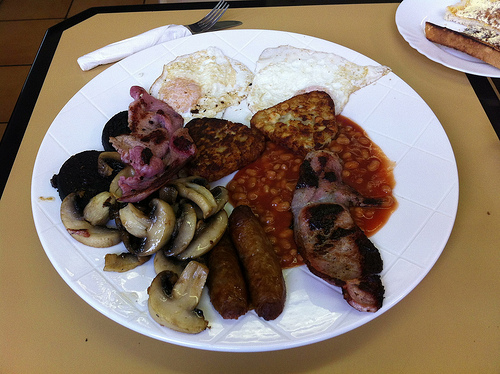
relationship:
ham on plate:
[291, 146, 390, 309] [31, 28, 459, 354]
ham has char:
[291, 146, 390, 309] [351, 235, 386, 295]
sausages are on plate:
[207, 207, 283, 320] [31, 28, 459, 354]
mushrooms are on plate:
[61, 180, 228, 332] [31, 28, 459, 354]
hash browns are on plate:
[187, 90, 337, 177] [31, 28, 459, 354]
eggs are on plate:
[157, 44, 352, 120] [31, 28, 459, 354]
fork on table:
[72, 0, 229, 67] [0, 1, 499, 372]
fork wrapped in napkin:
[72, 0, 229, 67] [75, 23, 190, 69]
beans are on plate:
[230, 115, 396, 263] [31, 28, 459, 354]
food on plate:
[58, 53, 388, 317] [31, 28, 459, 354]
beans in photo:
[230, 115, 396, 263] [0, 0, 498, 373]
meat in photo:
[213, 152, 385, 320] [0, 0, 498, 373]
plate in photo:
[31, 28, 459, 354] [0, 0, 498, 373]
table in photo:
[0, 1, 499, 372] [0, 0, 498, 373]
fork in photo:
[72, 0, 229, 67] [0, 0, 498, 373]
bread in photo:
[424, 0, 500, 70] [0, 0, 498, 373]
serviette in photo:
[75, 23, 190, 69] [0, 0, 498, 373]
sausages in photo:
[207, 207, 283, 320] [0, 0, 498, 373]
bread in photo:
[427, 0, 500, 66] [0, 0, 498, 373]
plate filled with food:
[31, 28, 459, 354] [58, 53, 388, 317]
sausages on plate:
[207, 207, 283, 320] [31, 28, 459, 354]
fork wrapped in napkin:
[76, 0, 229, 74] [75, 23, 190, 69]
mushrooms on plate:
[61, 180, 228, 332] [31, 28, 459, 354]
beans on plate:
[230, 115, 396, 263] [31, 28, 459, 354]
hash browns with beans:
[187, 90, 337, 177] [230, 115, 396, 263]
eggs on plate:
[157, 44, 352, 120] [31, 28, 459, 354]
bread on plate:
[427, 0, 500, 66] [394, 2, 499, 78]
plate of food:
[31, 28, 459, 354] [58, 53, 388, 317]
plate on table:
[31, 28, 459, 354] [0, 1, 499, 372]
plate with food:
[31, 28, 459, 354] [58, 53, 388, 317]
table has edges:
[0, 1, 499, 372] [0, 15, 68, 155]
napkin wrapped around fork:
[75, 23, 190, 69] [76, 0, 229, 74]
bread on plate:
[427, 0, 500, 66] [31, 28, 459, 354]